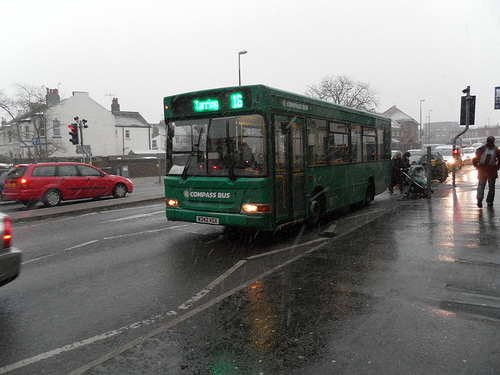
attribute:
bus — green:
[154, 82, 392, 236]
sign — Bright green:
[191, 85, 246, 115]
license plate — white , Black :
[188, 207, 224, 230]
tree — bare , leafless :
[300, 68, 388, 125]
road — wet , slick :
[2, 167, 497, 373]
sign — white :
[167, 162, 187, 180]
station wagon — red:
[1, 157, 137, 211]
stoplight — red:
[64, 114, 91, 161]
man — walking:
[468, 131, 499, 210]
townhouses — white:
[4, 84, 155, 154]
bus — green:
[384, 140, 437, 203]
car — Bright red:
[2, 159, 43, 209]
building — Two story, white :
[107, 108, 155, 153]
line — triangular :
[203, 241, 333, 279]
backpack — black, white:
[474, 140, 499, 172]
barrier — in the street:
[9, 193, 165, 219]